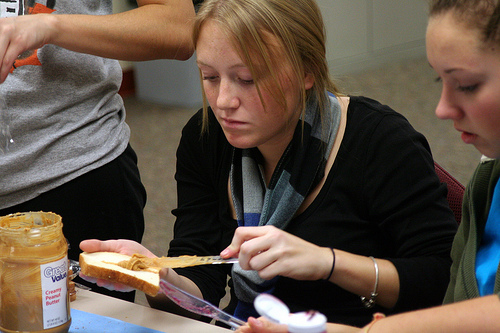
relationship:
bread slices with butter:
[78, 252, 161, 298] [113, 227, 180, 273]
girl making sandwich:
[97, 25, 435, 317] [79, 215, 221, 300]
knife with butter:
[169, 254, 237, 264] [0, 209, 213, 331]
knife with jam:
[157, 276, 243, 328] [163, 281, 212, 314]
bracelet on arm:
[360, 256, 380, 306] [219, 219, 398, 305]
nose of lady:
[434, 82, 460, 119] [241, 2, 497, 331]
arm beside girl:
[0, 2, 196, 73] [78, 0, 457, 333]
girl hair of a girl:
[189, 0, 347, 156] [78, 0, 457, 333]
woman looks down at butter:
[80, 0, 442, 331] [0, 209, 213, 331]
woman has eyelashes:
[80, 0, 442, 331] [199, 73, 260, 83]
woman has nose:
[223, 0, 497, 330] [434, 82, 464, 120]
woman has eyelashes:
[223, 0, 497, 330] [432, 73, 481, 91]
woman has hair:
[223, 0, 497, 330] [426, 0, 497, 45]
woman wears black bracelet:
[80, 0, 442, 331] [323, 247, 338, 280]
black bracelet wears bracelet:
[323, 247, 338, 280] [360, 255, 378, 305]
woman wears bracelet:
[223, 0, 497, 330] [367, 308, 384, 326]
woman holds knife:
[223, 0, 497, 330] [157, 276, 243, 328]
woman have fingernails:
[80, 0, 448, 333] [220, 248, 234, 254]